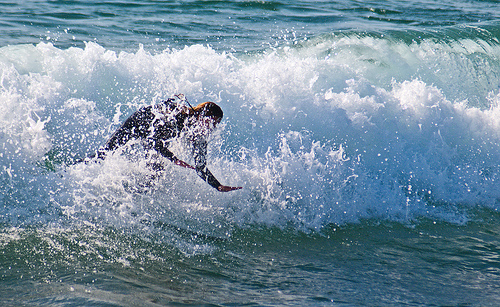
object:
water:
[0, 2, 500, 307]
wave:
[0, 29, 500, 264]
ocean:
[0, 1, 498, 299]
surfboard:
[71, 191, 235, 241]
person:
[73, 94, 246, 194]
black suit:
[74, 99, 221, 188]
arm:
[188, 129, 218, 192]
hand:
[218, 183, 243, 193]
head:
[190, 99, 226, 128]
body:
[74, 99, 218, 188]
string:
[175, 93, 197, 115]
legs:
[142, 148, 164, 194]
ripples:
[0, 231, 500, 292]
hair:
[191, 99, 228, 128]